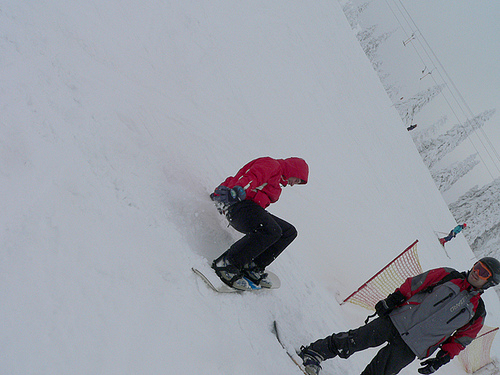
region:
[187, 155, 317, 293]
person in the snow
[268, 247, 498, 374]
person in the snow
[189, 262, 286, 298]
snowboard in the snow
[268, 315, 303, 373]
snowboard in the snow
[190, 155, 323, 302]
person wearing red jacket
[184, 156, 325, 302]
person wearing black pants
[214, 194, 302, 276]
pair of black pants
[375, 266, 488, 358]
red and grey coat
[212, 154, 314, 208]
red jacket with hood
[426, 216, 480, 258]
person on some skis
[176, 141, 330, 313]
Person falling down on a snowboard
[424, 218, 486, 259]
Person skiing in the background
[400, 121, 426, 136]
Person standing in the snow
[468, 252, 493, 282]
Orange and black snowboarding goggles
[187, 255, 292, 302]
White and blue snowboard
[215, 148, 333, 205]
Red and white coat with hood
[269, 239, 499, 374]
Man standing on a snowboard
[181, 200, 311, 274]
Black snowboarding pants on person's legs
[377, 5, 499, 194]
Wires above the snowy ground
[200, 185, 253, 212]
Gray snowboarding glove on person's hand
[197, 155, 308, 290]
a woman on a snowboard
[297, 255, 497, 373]
a man standing on a snowboard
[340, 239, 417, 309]
a orange net fence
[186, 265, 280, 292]
a white snowboard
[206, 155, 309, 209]
a pink coat on a woman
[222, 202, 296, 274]
black pants on a woman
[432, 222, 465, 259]
a person skiing in the distance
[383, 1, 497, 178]
cables of a ski lift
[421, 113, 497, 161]
a tall snow covered pine tree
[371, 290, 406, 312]
a black and gray glove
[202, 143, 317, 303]
This is a person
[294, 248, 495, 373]
This is a person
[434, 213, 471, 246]
This is a person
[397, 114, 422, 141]
This is a person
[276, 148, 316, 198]
Head of a person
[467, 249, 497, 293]
Head of a person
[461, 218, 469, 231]
Head of a person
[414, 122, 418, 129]
Head of a person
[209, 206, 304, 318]
Legs of a person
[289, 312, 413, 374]
Legs of a person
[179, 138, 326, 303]
guy falling on ground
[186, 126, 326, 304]
guy falling on white snow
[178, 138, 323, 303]
guy wearing red jacket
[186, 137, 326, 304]
guy wearing black pants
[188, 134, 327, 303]
guy on snowboard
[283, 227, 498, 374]
guy wearing black helmet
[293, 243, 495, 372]
guy wearing red and grey jacket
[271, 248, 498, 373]
guy wearing dark grey pants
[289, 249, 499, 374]
guy wearing a ski mask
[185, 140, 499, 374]
two guys snowboarding